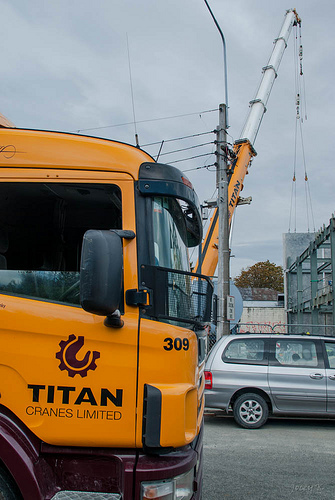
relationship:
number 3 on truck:
[162, 336, 172, 350] [0, 127, 212, 499]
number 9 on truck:
[183, 337, 190, 349] [3, 6, 300, 498]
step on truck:
[45, 469, 132, 498] [0, 127, 212, 499]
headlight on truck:
[141, 465, 193, 498] [0, 127, 212, 499]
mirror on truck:
[82, 222, 134, 334] [0, 127, 212, 499]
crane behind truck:
[190, 7, 302, 283] [0, 127, 212, 499]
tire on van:
[231, 393, 267, 431] [211, 331, 322, 419]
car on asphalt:
[219, 322, 309, 432] [202, 416, 335, 499]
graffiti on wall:
[237, 318, 289, 337] [231, 302, 285, 344]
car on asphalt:
[204, 332, 334, 429] [202, 416, 335, 499]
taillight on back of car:
[204, 368, 214, 390] [202, 331, 334, 428]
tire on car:
[233, 393, 268, 428] [202, 331, 324, 422]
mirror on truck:
[80, 225, 123, 316] [0, 127, 212, 499]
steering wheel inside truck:
[60, 279, 83, 304] [0, 127, 212, 499]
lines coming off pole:
[154, 106, 214, 172] [218, 101, 234, 336]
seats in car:
[290, 342, 313, 361] [196, 298, 332, 440]